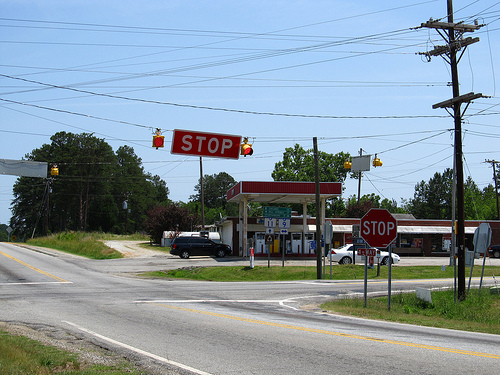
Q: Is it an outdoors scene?
A: Yes, it is outdoors.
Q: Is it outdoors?
A: Yes, it is outdoors.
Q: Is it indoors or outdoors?
A: It is outdoors.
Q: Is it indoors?
A: No, it is outdoors.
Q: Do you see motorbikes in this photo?
A: No, there are no motorbikes.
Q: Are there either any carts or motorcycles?
A: No, there are no motorcycles or carts.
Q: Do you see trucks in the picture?
A: No, there are no trucks.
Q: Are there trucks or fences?
A: No, there are no trucks or fences.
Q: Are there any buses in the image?
A: No, there are no buses.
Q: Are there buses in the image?
A: No, there are no buses.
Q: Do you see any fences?
A: No, there are no fences.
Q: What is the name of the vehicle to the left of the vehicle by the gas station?
A: The vehicle is a SUV.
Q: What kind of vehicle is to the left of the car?
A: The vehicle is a SUV.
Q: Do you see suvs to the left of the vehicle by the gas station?
A: Yes, there is a SUV to the left of the car.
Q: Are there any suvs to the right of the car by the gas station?
A: No, the SUV is to the left of the car.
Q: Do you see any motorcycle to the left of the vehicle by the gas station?
A: No, there is a SUV to the left of the car.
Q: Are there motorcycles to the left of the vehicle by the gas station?
A: No, there is a SUV to the left of the car.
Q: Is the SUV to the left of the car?
A: Yes, the SUV is to the left of the car.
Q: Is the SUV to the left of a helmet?
A: No, the SUV is to the left of the car.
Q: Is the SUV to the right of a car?
A: No, the SUV is to the left of a car.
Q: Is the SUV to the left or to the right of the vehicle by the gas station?
A: The SUV is to the left of the car.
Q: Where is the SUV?
A: The SUV is at the gas station.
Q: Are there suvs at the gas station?
A: Yes, there is a SUV at the gas station.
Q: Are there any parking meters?
A: No, there are no parking meters.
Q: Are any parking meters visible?
A: No, there are no parking meters.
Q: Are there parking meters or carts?
A: No, there are no parking meters or carts.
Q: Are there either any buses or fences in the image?
A: No, there are no fences or buses.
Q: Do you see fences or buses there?
A: No, there are no fences or buses.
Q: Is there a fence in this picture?
A: No, there are no fences.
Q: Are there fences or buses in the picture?
A: No, there are no fences or buses.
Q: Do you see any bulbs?
A: No, there are no bulbs.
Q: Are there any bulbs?
A: No, there are no bulbs.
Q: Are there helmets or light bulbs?
A: No, there are no light bulbs or helmets.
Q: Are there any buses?
A: No, there are no buses.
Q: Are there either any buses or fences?
A: No, there are no buses or fences.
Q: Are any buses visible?
A: No, there are no buses.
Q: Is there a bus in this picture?
A: No, there are no buses.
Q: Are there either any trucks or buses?
A: No, there are no buses or trucks.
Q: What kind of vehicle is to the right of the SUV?
A: The vehicle is a car.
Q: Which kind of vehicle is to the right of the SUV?
A: The vehicle is a car.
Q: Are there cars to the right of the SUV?
A: Yes, there is a car to the right of the SUV.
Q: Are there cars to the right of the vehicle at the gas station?
A: Yes, there is a car to the right of the SUV.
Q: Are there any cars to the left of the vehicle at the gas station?
A: No, the car is to the right of the SUV.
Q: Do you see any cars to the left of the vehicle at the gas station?
A: No, the car is to the right of the SUV.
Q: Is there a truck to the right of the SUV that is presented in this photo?
A: No, there is a car to the right of the SUV.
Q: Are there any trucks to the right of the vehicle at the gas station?
A: No, there is a car to the right of the SUV.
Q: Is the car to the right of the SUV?
A: Yes, the car is to the right of the SUV.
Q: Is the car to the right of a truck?
A: No, the car is to the right of the SUV.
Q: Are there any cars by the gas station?
A: Yes, there is a car by the gas station.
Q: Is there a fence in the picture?
A: No, there are no fences.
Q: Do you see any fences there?
A: No, there are no fences.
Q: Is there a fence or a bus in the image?
A: No, there are no fences or buses.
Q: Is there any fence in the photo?
A: No, there are no fences.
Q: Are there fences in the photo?
A: No, there are no fences.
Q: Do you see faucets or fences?
A: No, there are no fences or faucets.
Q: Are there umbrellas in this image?
A: No, there are no umbrellas.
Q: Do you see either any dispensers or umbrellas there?
A: No, there are no umbrellas or dispensers.